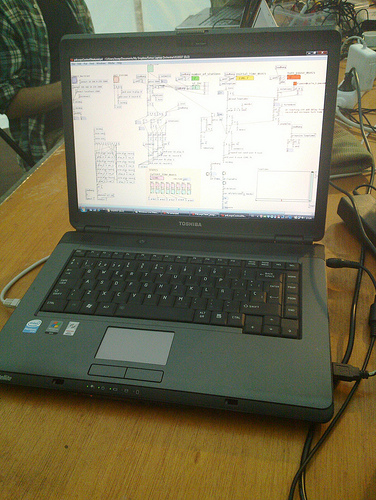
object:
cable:
[325, 254, 375, 274]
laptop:
[0, 26, 343, 422]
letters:
[95, 277, 114, 291]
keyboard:
[39, 248, 303, 338]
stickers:
[63, 321, 80, 337]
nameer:
[176, 218, 206, 229]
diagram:
[69, 49, 329, 219]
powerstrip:
[345, 42, 376, 94]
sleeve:
[0, 0, 29, 115]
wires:
[312, 0, 371, 37]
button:
[280, 317, 301, 338]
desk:
[0, 0, 376, 498]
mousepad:
[94, 325, 176, 366]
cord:
[327, 256, 375, 279]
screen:
[69, 48, 329, 221]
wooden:
[25, 178, 56, 236]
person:
[0, 0, 97, 174]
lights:
[86, 384, 88, 389]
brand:
[179, 220, 202, 227]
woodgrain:
[22, 184, 53, 226]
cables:
[295, 1, 365, 28]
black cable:
[331, 356, 369, 383]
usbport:
[328, 358, 335, 380]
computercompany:
[180, 219, 204, 228]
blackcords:
[324, 257, 366, 378]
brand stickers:
[22, 319, 42, 334]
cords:
[349, 64, 376, 192]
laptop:
[174, 0, 248, 30]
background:
[0, 0, 376, 28]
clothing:
[331, 115, 375, 175]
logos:
[44, 318, 62, 335]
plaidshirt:
[1, 0, 99, 175]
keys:
[154, 274, 172, 284]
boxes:
[74, 77, 304, 81]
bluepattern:
[147, 174, 203, 195]